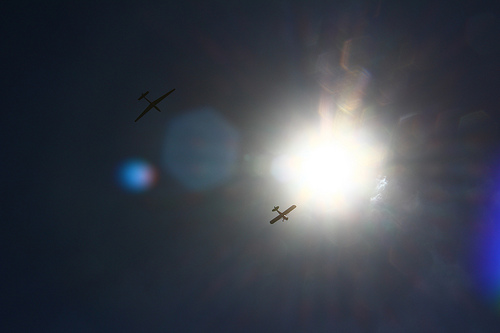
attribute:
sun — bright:
[259, 112, 397, 217]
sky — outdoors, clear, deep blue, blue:
[11, 9, 498, 330]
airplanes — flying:
[128, 86, 300, 235]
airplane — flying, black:
[133, 82, 178, 124]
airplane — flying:
[266, 203, 300, 230]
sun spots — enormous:
[109, 111, 303, 193]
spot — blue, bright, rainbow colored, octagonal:
[115, 155, 163, 195]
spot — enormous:
[159, 105, 244, 194]